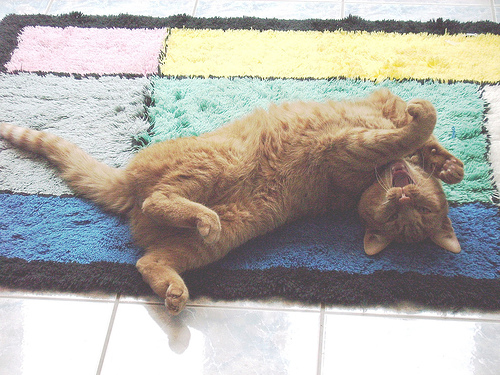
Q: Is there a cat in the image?
A: Yes, there is a cat.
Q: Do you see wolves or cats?
A: Yes, there is a cat.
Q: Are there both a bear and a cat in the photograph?
A: No, there is a cat but no bears.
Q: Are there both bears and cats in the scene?
A: No, there is a cat but no bears.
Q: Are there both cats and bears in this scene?
A: No, there is a cat but no bears.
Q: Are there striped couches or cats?
A: Yes, there is a striped cat.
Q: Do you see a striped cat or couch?
A: Yes, there is a striped cat.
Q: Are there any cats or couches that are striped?
A: Yes, the cat is striped.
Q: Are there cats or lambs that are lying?
A: Yes, the cat is lying.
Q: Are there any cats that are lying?
A: Yes, there is a cat that is lying.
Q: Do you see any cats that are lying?
A: Yes, there is a cat that is lying.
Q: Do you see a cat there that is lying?
A: Yes, there is a cat that is lying.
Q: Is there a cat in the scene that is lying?
A: Yes, there is a cat that is lying.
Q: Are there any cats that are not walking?
A: Yes, there is a cat that is lying.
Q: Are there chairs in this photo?
A: No, there are no chairs.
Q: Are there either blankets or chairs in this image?
A: No, there are no chairs or blankets.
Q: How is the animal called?
A: The animal is a cat.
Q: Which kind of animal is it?
A: The animal is a cat.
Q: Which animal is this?
A: This is a cat.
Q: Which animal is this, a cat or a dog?
A: This is a cat.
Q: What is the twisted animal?
A: The animal is a cat.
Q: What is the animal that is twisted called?
A: The animal is a cat.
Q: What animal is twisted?
A: The animal is a cat.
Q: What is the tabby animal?
A: The animal is a cat.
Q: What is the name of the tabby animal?
A: The animal is a cat.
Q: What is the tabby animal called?
A: The animal is a cat.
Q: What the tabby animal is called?
A: The animal is a cat.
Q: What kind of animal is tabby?
A: The animal is a cat.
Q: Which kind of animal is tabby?
A: The animal is a cat.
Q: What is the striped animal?
A: The animal is a cat.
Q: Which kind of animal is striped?
A: The animal is a cat.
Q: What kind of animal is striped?
A: The animal is a cat.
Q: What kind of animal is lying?
A: The animal is a cat.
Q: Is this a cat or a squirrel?
A: This is a cat.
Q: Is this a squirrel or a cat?
A: This is a cat.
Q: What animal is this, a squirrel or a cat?
A: This is a cat.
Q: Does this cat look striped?
A: Yes, the cat is striped.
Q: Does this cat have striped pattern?
A: Yes, the cat is striped.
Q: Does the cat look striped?
A: Yes, the cat is striped.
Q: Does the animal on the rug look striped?
A: Yes, the cat is striped.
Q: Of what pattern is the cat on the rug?
A: The cat is striped.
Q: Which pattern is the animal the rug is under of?
A: The cat is striped.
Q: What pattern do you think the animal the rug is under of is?
A: The cat is striped.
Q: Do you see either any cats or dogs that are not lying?
A: No, there is a cat but it is lying.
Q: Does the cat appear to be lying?
A: Yes, the cat is lying.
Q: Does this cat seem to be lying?
A: Yes, the cat is lying.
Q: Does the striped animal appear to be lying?
A: Yes, the cat is lying.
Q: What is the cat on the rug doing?
A: The cat is lying.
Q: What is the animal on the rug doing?
A: The cat is lying.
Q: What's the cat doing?
A: The cat is lying.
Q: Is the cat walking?
A: No, the cat is lying.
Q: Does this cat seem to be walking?
A: No, the cat is lying.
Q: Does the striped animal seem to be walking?
A: No, the cat is lying.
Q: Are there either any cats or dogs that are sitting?
A: No, there is a cat but it is lying.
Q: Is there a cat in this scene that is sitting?
A: No, there is a cat but it is lying.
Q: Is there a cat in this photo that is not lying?
A: No, there is a cat but it is lying.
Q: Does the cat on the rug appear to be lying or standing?
A: The cat is lying.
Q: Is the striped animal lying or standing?
A: The cat is lying.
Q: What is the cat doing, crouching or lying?
A: The cat is lying.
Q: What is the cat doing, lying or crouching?
A: The cat is lying.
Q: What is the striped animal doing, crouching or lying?
A: The cat is lying.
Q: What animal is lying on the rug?
A: The animal is a cat.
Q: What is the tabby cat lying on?
A: The cat is lying on the rug.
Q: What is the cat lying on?
A: The cat is lying on the rug.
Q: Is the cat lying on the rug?
A: Yes, the cat is lying on the rug.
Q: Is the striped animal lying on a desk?
A: No, the cat is lying on the rug.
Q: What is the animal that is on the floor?
A: The animal is a cat.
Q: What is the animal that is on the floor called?
A: The animal is a cat.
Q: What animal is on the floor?
A: The animal is a cat.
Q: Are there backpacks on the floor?
A: No, there is a cat on the floor.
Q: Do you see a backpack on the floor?
A: No, there is a cat on the floor.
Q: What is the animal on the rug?
A: The animal is a cat.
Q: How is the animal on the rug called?
A: The animal is a cat.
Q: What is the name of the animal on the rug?
A: The animal is a cat.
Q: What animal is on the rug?
A: The animal is a cat.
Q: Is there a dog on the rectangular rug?
A: No, there is a cat on the rug.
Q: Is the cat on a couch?
A: No, the cat is on the rug.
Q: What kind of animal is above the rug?
A: The animal is a cat.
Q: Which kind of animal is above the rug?
A: The animal is a cat.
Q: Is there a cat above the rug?
A: Yes, there is a cat above the rug.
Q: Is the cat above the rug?
A: Yes, the cat is above the rug.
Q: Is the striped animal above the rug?
A: Yes, the cat is above the rug.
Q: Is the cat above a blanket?
A: No, the cat is above the rug.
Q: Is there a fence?
A: No, there are no fences.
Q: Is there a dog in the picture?
A: No, there are no dogs.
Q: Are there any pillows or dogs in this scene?
A: No, there are no dogs or pillows.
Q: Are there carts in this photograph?
A: No, there are no carts.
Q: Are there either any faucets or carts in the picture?
A: No, there are no carts or faucets.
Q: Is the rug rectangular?
A: Yes, the rug is rectangular.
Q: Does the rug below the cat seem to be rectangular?
A: Yes, the rug is rectangular.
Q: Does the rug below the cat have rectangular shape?
A: Yes, the rug is rectangular.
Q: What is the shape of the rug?
A: The rug is rectangular.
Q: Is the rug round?
A: No, the rug is rectangular.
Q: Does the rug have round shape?
A: No, the rug is rectangular.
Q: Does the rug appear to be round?
A: No, the rug is rectangular.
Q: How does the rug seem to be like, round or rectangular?
A: The rug is rectangular.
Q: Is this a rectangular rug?
A: Yes, this is a rectangular rug.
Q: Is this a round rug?
A: No, this is a rectangular rug.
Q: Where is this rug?
A: The rug is on the floor.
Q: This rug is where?
A: The rug is on the floor.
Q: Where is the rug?
A: The rug is on the floor.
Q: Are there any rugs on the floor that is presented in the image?
A: Yes, there is a rug on the floor.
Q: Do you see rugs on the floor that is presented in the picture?
A: Yes, there is a rug on the floor.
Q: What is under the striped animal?
A: The rug is under the cat.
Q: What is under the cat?
A: The rug is under the cat.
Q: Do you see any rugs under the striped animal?
A: Yes, there is a rug under the cat.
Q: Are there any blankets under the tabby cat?
A: No, there is a rug under the cat.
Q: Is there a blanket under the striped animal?
A: No, there is a rug under the cat.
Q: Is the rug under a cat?
A: Yes, the rug is under a cat.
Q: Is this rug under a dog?
A: No, the rug is under a cat.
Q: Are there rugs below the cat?
A: Yes, there is a rug below the cat.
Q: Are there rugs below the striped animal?
A: Yes, there is a rug below the cat.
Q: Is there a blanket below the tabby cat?
A: No, there is a rug below the cat.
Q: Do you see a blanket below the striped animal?
A: No, there is a rug below the cat.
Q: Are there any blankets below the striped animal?
A: No, there is a rug below the cat.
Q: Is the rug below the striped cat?
A: Yes, the rug is below the cat.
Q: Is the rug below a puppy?
A: No, the rug is below the cat.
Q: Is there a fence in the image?
A: No, there are no fences.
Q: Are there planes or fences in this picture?
A: No, there are no fences or planes.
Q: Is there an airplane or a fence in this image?
A: No, there are no fences or airplanes.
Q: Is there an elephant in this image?
A: No, there are no elephants.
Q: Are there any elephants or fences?
A: No, there are no elephants or fences.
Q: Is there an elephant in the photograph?
A: No, there are no elephants.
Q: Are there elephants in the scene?
A: No, there are no elephants.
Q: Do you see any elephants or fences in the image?
A: No, there are no elephants or fences.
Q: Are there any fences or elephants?
A: No, there are no elephants or fences.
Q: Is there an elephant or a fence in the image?
A: No, there are no elephants or fences.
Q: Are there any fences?
A: No, there are no fences.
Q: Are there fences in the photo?
A: No, there are no fences.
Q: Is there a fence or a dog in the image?
A: No, there are no fences or dogs.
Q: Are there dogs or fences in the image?
A: No, there are no fences or dogs.